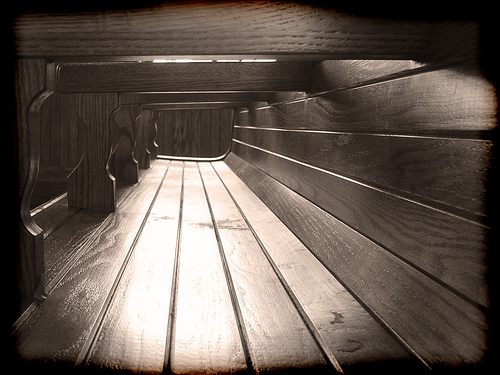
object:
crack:
[207, 161, 347, 373]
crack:
[193, 159, 256, 367]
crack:
[162, 159, 187, 371]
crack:
[78, 159, 173, 366]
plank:
[81, 158, 184, 374]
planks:
[208, 156, 427, 371]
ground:
[444, 142, 464, 162]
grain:
[182, 196, 212, 231]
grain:
[148, 196, 178, 229]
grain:
[266, 176, 306, 242]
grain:
[340, 192, 484, 268]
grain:
[370, 242, 490, 332]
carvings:
[194, 216, 251, 232]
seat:
[3, 2, 498, 109]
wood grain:
[245, 148, 411, 320]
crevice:
[228, 149, 500, 323]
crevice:
[229, 137, 494, 229]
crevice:
[230, 123, 497, 143]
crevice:
[217, 157, 435, 375]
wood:
[0, 0, 500, 375]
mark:
[330, 312, 348, 325]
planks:
[208, 156, 418, 374]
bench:
[0, 0, 498, 374]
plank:
[64, 92, 120, 212]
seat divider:
[14, 7, 500, 375]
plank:
[13, 54, 57, 311]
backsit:
[225, 57, 500, 360]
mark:
[159, 215, 177, 223]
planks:
[220, 147, 496, 375]